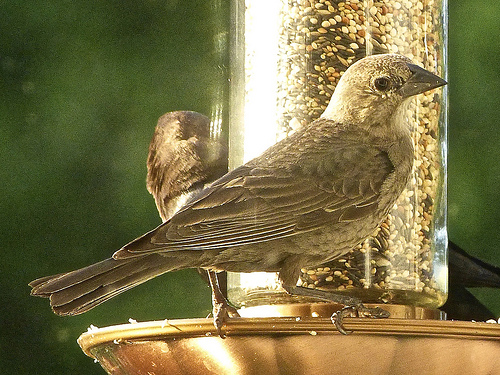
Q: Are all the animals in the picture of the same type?
A: Yes, all the animals are birds.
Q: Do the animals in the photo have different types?
A: No, all the animals are birds.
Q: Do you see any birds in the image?
A: Yes, there is a bird.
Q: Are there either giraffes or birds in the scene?
A: Yes, there is a bird.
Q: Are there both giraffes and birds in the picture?
A: No, there is a bird but no giraffes.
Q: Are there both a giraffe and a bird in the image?
A: No, there is a bird but no giraffes.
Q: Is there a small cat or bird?
A: Yes, there is a small bird.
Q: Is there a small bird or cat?
A: Yes, there is a small bird.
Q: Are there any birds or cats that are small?
A: Yes, the bird is small.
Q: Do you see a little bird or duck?
A: Yes, there is a little bird.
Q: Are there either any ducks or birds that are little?
A: Yes, the bird is little.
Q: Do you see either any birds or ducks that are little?
A: Yes, the bird is little.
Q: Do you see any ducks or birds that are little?
A: Yes, the bird is little.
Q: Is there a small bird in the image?
A: Yes, there is a small bird.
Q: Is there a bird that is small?
A: Yes, there is a bird that is small.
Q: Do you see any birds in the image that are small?
A: Yes, there is a bird that is small.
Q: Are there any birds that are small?
A: Yes, there is a bird that is small.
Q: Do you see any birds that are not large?
A: Yes, there is a small bird.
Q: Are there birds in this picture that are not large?
A: Yes, there is a small bird.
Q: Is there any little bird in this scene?
A: Yes, there is a little bird.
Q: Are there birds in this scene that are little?
A: Yes, there is a bird that is little.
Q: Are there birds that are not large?
A: Yes, there is a little bird.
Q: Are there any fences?
A: No, there are no fences.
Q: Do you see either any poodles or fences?
A: No, there are no fences or poodles.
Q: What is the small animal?
A: The animal is a bird.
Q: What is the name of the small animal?
A: The animal is a bird.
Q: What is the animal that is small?
A: The animal is a bird.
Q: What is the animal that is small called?
A: The animal is a bird.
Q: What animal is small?
A: The animal is a bird.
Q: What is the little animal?
A: The animal is a bird.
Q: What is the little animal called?
A: The animal is a bird.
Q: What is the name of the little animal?
A: The animal is a bird.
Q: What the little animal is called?
A: The animal is a bird.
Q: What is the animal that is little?
A: The animal is a bird.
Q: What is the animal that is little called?
A: The animal is a bird.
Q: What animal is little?
A: The animal is a bird.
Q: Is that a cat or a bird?
A: That is a bird.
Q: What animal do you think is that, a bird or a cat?
A: That is a bird.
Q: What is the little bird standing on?
A: The bird is standing on the feeder.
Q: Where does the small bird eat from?
A: The bird eats from the feeder.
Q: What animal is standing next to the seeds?
A: The bird is standing next to the seeds.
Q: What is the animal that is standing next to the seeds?
A: The animal is a bird.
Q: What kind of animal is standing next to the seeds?
A: The animal is a bird.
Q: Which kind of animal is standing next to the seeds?
A: The animal is a bird.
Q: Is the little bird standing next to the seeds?
A: Yes, the bird is standing next to the seeds.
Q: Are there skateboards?
A: No, there are no skateboards.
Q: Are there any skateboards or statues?
A: No, there are no skateboards or statues.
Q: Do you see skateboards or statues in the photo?
A: No, there are no skateboards or statues.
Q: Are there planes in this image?
A: No, there are no planes.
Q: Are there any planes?
A: No, there are no planes.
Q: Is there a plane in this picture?
A: No, there are no airplanes.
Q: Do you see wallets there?
A: No, there are no wallets.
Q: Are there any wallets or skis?
A: No, there are no wallets or skis.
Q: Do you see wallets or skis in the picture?
A: No, there are no wallets or skis.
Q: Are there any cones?
A: No, there are no cones.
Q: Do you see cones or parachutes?
A: No, there are no cones or parachutes.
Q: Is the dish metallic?
A: Yes, the dish is metallic.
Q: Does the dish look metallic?
A: Yes, the dish is metallic.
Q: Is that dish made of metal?
A: Yes, the dish is made of metal.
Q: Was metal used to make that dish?
A: Yes, the dish is made of metal.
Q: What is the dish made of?
A: The dish is made of metal.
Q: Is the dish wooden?
A: No, the dish is metallic.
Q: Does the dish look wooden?
A: No, the dish is metallic.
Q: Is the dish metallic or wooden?
A: The dish is metallic.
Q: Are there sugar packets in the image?
A: No, there are no sugar packets.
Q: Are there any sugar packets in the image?
A: No, there are no sugar packets.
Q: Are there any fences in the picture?
A: No, there are no fences.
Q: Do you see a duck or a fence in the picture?
A: No, there are no fences or ducks.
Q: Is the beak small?
A: Yes, the beak is small.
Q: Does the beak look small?
A: Yes, the beak is small.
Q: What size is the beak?
A: The beak is small.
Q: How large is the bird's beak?
A: The beak is small.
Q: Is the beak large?
A: No, the beak is small.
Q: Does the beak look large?
A: No, the beak is small.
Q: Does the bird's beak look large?
A: No, the beak is small.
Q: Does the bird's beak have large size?
A: No, the beak is small.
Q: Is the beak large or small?
A: The beak is small.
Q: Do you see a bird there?
A: Yes, there are birds.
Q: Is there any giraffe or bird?
A: Yes, there are birds.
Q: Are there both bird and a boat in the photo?
A: No, there are birds but no boats.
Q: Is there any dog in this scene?
A: No, there are no dogs.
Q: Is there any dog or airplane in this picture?
A: No, there are no dogs or airplanes.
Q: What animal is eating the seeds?
A: The birds are eating the seeds.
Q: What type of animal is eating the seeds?
A: The animals are birds.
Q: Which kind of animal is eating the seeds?
A: The animals are birds.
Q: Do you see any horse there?
A: No, there are no horses.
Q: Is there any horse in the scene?
A: No, there are no horses.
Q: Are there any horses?
A: No, there are no horses.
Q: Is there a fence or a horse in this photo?
A: No, there are no horses or fences.